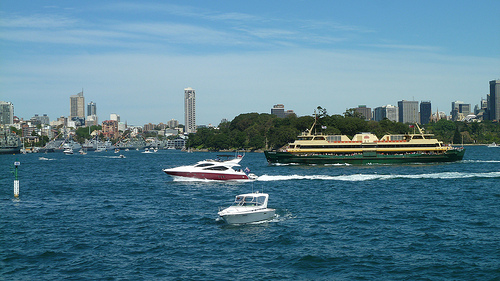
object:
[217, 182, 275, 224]
boat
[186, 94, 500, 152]
trees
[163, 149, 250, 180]
boat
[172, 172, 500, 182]
wave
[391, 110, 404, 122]
ground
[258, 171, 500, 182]
wake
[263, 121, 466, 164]
boat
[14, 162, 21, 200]
object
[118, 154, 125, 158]
boat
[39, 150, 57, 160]
boat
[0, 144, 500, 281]
water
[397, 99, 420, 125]
building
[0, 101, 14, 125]
building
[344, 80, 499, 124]
buildings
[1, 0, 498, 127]
clouds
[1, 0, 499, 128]
sky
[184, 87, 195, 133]
building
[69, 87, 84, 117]
building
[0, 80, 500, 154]
city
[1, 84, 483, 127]
skyline